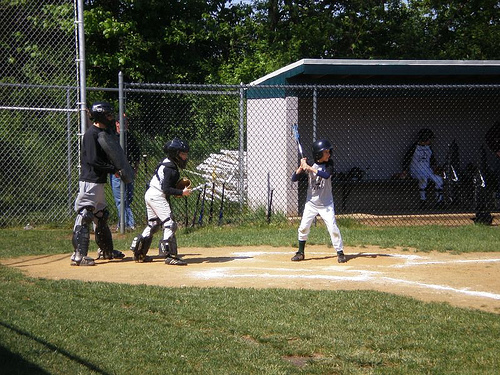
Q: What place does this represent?
A: It represents the field.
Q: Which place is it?
A: It is a field.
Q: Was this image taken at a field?
A: Yes, it was taken in a field.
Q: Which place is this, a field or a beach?
A: It is a field.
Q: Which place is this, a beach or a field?
A: It is a field.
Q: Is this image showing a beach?
A: No, the picture is showing a field.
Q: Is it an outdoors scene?
A: Yes, it is outdoors.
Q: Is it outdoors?
A: Yes, it is outdoors.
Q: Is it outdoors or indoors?
A: It is outdoors.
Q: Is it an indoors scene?
A: No, it is outdoors.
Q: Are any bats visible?
A: Yes, there is a bat.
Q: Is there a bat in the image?
A: Yes, there is a bat.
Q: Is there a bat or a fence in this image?
A: Yes, there is a bat.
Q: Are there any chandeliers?
A: No, there are no chandeliers.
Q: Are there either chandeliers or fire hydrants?
A: No, there are no chandeliers or fire hydrants.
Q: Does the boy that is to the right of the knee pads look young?
A: Yes, the boy is young.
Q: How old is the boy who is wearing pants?
A: The boy is young.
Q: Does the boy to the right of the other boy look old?
A: No, the boy is young.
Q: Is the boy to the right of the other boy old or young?
A: The boy is young.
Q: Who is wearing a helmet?
A: The boy is wearing a helmet.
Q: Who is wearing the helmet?
A: The boy is wearing a helmet.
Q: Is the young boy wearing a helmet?
A: Yes, the boy is wearing a helmet.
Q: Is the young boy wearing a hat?
A: No, the boy is wearing a helmet.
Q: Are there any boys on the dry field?
A: Yes, there is a boy on the field.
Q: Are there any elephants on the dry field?
A: No, there is a boy on the field.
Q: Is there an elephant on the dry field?
A: No, there is a boy on the field.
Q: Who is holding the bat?
A: The boy is holding the bat.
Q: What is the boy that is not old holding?
A: The boy is holding the bat.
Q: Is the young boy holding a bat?
A: Yes, the boy is holding a bat.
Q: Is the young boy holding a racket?
A: No, the boy is holding a bat.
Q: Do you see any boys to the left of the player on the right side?
A: Yes, there is a boy to the left of the player.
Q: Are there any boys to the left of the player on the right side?
A: Yes, there is a boy to the left of the player.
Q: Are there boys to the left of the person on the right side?
A: Yes, there is a boy to the left of the player.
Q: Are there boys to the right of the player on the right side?
A: No, the boy is to the left of the player.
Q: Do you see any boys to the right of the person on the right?
A: No, the boy is to the left of the player.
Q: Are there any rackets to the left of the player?
A: No, there is a boy to the left of the player.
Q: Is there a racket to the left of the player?
A: No, there is a boy to the left of the player.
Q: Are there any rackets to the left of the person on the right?
A: No, there is a boy to the left of the player.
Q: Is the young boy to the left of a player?
A: Yes, the boy is to the left of a player.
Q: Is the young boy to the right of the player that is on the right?
A: No, the boy is to the left of the player.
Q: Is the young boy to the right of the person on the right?
A: No, the boy is to the left of the player.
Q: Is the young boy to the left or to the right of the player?
A: The boy is to the left of the player.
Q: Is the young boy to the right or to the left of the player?
A: The boy is to the left of the player.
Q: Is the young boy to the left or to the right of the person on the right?
A: The boy is to the left of the player.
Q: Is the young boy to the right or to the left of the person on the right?
A: The boy is to the left of the player.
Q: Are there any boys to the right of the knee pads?
A: Yes, there is a boy to the right of the knee pads.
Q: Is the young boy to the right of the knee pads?
A: Yes, the boy is to the right of the knee pads.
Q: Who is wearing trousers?
A: The boy is wearing trousers.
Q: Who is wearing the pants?
A: The boy is wearing trousers.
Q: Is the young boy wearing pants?
A: Yes, the boy is wearing pants.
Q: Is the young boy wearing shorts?
A: No, the boy is wearing pants.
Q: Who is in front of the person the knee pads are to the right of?
A: The boy is in front of the umpire.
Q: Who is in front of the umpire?
A: The boy is in front of the umpire.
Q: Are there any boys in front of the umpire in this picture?
A: Yes, there is a boy in front of the umpire.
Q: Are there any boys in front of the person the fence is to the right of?
A: Yes, there is a boy in front of the umpire.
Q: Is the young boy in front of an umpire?
A: Yes, the boy is in front of an umpire.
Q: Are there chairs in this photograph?
A: No, there are no chairs.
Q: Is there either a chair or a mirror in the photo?
A: No, there are no chairs or mirrors.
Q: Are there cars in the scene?
A: No, there are no cars.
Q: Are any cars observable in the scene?
A: No, there are no cars.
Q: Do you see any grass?
A: Yes, there is grass.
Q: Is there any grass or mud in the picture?
A: Yes, there is grass.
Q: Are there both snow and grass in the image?
A: No, there is grass but no snow.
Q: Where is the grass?
A: The grass is on the field.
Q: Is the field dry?
A: Yes, the field is dry.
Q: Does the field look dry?
A: Yes, the field is dry.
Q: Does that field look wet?
A: No, the field is dry.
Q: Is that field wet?
A: No, the field is dry.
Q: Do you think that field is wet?
A: No, the field is dry.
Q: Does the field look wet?
A: No, the field is dry.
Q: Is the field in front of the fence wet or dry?
A: The field is dry.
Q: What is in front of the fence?
A: The field is in front of the fence.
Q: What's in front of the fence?
A: The field is in front of the fence.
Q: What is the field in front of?
A: The field is in front of the fence.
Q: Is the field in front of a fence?
A: Yes, the field is in front of a fence.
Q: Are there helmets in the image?
A: Yes, there is a helmet.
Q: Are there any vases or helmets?
A: Yes, there is a helmet.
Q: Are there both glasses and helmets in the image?
A: No, there is a helmet but no glasses.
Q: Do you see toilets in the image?
A: No, there are no toilets.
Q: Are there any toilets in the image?
A: No, there are no toilets.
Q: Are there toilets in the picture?
A: No, there are no toilets.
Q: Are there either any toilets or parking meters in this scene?
A: No, there are no toilets or parking meters.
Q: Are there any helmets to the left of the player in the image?
A: Yes, there is a helmet to the left of the player.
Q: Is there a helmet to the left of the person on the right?
A: Yes, there is a helmet to the left of the player.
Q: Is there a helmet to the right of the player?
A: No, the helmet is to the left of the player.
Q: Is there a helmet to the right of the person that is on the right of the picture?
A: No, the helmet is to the left of the player.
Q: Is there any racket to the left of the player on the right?
A: No, there is a helmet to the left of the player.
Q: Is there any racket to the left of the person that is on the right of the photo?
A: No, there is a helmet to the left of the player.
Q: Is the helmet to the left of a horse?
A: No, the helmet is to the left of the player.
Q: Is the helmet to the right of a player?
A: No, the helmet is to the left of a player.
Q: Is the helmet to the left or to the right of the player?
A: The helmet is to the left of the player.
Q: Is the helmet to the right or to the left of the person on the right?
A: The helmet is to the left of the player.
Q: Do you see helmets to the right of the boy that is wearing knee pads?
A: Yes, there is a helmet to the right of the boy.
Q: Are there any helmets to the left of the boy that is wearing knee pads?
A: No, the helmet is to the right of the boy.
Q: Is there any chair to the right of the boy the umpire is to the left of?
A: No, there is a helmet to the right of the boy.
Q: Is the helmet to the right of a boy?
A: Yes, the helmet is to the right of a boy.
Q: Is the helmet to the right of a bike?
A: No, the helmet is to the right of a boy.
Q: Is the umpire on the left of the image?
A: Yes, the umpire is on the left of the image.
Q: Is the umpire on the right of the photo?
A: No, the umpire is on the left of the image.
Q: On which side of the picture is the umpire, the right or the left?
A: The umpire is on the left of the image.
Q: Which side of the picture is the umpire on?
A: The umpire is on the left of the image.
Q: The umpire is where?
A: The umpire is on the field.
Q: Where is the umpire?
A: The umpire is on the field.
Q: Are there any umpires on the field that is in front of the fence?
A: Yes, there is an umpire on the field.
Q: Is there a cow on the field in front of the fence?
A: No, there is an umpire on the field.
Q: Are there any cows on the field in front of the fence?
A: No, there is an umpire on the field.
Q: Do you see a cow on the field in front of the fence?
A: No, there is an umpire on the field.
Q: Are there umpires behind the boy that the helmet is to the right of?
A: Yes, there is an umpire behind the boy.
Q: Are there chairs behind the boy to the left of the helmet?
A: No, there is an umpire behind the boy.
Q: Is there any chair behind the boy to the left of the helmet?
A: No, there is an umpire behind the boy.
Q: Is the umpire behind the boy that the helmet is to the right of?
A: Yes, the umpire is behind the boy.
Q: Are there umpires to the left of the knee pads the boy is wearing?
A: Yes, there is an umpire to the left of the knee pads.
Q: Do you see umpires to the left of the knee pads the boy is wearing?
A: Yes, there is an umpire to the left of the knee pads.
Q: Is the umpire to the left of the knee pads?
A: Yes, the umpire is to the left of the knee pads.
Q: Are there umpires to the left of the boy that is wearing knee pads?
A: Yes, there is an umpire to the left of the boy.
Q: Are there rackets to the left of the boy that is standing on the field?
A: No, there is an umpire to the left of the boy.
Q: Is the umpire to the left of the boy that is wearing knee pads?
A: Yes, the umpire is to the left of the boy.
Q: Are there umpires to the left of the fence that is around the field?
A: Yes, there is an umpire to the left of the fence.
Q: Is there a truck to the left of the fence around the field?
A: No, there is an umpire to the left of the fence.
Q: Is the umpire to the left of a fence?
A: Yes, the umpire is to the left of a fence.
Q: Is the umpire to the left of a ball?
A: No, the umpire is to the left of a fence.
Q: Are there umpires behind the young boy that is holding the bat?
A: Yes, there is an umpire behind the boy.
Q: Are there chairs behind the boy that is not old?
A: No, there is an umpire behind the boy.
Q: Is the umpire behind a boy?
A: Yes, the umpire is behind a boy.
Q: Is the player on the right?
A: Yes, the player is on the right of the image.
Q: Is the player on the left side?
A: No, the player is on the right of the image.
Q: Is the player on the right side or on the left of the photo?
A: The player is on the right of the image.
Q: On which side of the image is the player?
A: The player is on the right of the image.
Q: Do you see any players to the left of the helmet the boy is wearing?
A: No, the player is to the right of the helmet.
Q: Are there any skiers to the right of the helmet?
A: No, there is a player to the right of the helmet.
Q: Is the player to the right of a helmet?
A: Yes, the player is to the right of a helmet.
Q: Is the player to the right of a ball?
A: No, the player is to the right of a helmet.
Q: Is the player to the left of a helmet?
A: No, the player is to the right of a helmet.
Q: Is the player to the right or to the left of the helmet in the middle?
A: The player is to the right of the helmet.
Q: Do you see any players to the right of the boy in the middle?
A: Yes, there is a player to the right of the boy.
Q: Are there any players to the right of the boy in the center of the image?
A: Yes, there is a player to the right of the boy.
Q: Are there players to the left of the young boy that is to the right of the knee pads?
A: No, the player is to the right of the boy.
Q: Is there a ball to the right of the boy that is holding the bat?
A: No, there is a player to the right of the boy.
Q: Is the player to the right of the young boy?
A: Yes, the player is to the right of the boy.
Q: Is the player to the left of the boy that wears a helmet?
A: No, the player is to the right of the boy.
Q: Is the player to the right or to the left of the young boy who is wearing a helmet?
A: The player is to the right of the boy.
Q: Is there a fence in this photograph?
A: Yes, there is a fence.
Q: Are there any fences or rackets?
A: Yes, there is a fence.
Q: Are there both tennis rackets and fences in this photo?
A: No, there is a fence but no rackets.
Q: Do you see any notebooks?
A: No, there are no notebooks.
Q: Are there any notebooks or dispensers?
A: No, there are no notebooks or dispensers.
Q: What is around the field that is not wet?
A: The fence is around the field.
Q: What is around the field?
A: The fence is around the field.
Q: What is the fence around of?
A: The fence is around the field.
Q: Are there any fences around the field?
A: Yes, there is a fence around the field.